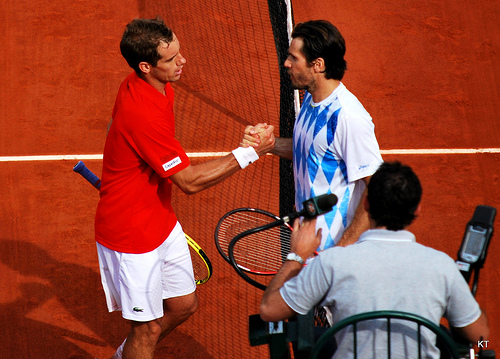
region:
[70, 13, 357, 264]
two tennis players shaking hands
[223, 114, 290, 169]
two hands are shaking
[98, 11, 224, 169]
tennis player has black hair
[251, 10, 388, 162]
tennis player has black hair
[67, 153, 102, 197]
the handle is blue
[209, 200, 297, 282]
head of racket is black and red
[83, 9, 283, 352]
man has red shirt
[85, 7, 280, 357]
player wears white shorts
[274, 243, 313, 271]
a clock on wrist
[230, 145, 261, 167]
a white wristband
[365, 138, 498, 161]
a long white line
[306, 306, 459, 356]
part of a green chair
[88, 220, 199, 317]
a man's white shorts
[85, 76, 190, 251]
a man's red shirt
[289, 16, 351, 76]
a man's short cut black hair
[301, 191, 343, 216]
a microphone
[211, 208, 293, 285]
part of a tennis racket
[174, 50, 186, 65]
the nose of a man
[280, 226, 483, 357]
a man's gray shirt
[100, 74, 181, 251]
The red shirt of the player.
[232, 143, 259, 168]
The white sweatband on the player's wrist.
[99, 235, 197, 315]
The white shorts the player is wearing.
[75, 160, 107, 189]
The blue handle of the tennis racquet.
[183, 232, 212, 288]
The yellow and black frame of the tennis racquet.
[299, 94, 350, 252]
The blue design on the player's shirt.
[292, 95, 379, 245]
The white shirt the player is wearing.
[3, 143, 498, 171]
The white boundary line of the court.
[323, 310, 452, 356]
The green chair the man is sitting on.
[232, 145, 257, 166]
wrist on the man's wrist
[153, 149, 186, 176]
design on man's shirt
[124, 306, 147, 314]
logo on the man's shorts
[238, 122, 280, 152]
two man's hands clasped together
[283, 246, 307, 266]
watch on the man's wrist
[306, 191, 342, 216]
microphone attached to a chair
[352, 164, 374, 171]
logo on the man's shirt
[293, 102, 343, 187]
design on the shirt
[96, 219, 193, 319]
shorts on the man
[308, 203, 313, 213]
logo on the microphone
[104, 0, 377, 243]
two people holding hands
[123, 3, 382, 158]
two people shaking hands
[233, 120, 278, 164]
hands grasped together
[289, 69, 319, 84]
brown beard on face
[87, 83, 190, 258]
red shirt on man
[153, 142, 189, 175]
white logo on side of shirt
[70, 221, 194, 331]
white shorts on man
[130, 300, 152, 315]
black logo on shorts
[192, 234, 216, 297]
yellow and black racket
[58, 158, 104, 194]
blue handle of racket